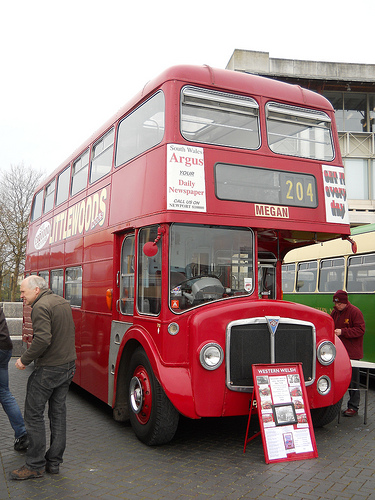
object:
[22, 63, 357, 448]
bus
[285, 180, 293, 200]
number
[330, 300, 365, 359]
coat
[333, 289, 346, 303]
cap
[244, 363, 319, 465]
sign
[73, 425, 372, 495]
parking space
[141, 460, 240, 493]
gray color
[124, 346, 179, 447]
wheel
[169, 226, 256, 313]
windshield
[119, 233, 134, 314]
side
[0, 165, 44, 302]
no leaves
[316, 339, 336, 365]
headlight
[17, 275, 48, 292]
hair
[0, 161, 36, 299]
tree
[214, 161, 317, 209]
display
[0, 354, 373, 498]
floor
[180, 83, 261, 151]
window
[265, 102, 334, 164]
window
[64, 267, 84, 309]
window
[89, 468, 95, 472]
debris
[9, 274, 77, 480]
man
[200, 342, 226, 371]
headlight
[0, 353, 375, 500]
ground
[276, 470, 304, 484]
concrete bricks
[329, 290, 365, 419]
man